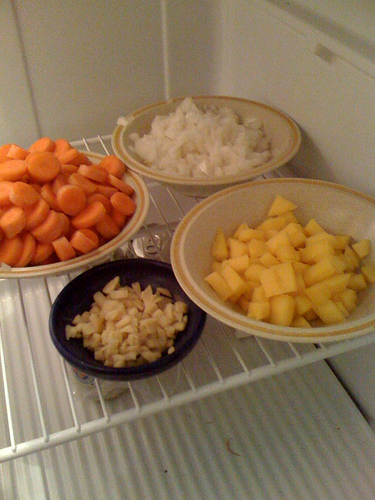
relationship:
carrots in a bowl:
[0, 138, 136, 265] [1, 149, 151, 282]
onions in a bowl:
[133, 99, 270, 180] [114, 95, 304, 190]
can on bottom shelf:
[131, 224, 178, 259] [1, 282, 371, 496]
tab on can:
[143, 233, 161, 251] [131, 224, 178, 259]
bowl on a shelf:
[49, 258, 204, 378] [1, 128, 373, 460]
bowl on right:
[114, 95, 304, 190] [154, 78, 374, 408]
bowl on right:
[171, 180, 374, 344] [154, 78, 374, 408]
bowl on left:
[1, 149, 151, 282] [0, 139, 197, 497]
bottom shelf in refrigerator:
[1, 282, 371, 496] [4, 2, 367, 496]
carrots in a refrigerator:
[0, 138, 136, 265] [4, 2, 367, 496]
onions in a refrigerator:
[133, 99, 270, 180] [4, 2, 367, 496]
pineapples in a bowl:
[206, 198, 368, 327] [171, 180, 374, 344]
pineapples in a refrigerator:
[206, 198, 368, 327] [4, 2, 367, 496]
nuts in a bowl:
[64, 277, 189, 365] [49, 258, 204, 378]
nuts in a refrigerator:
[64, 277, 189, 365] [4, 2, 367, 496]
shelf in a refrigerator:
[1, 128, 373, 460] [4, 2, 367, 496]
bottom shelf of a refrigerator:
[1, 282, 371, 496] [4, 2, 367, 496]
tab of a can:
[143, 233, 161, 251] [131, 224, 178, 259]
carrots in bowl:
[0, 138, 136, 265] [1, 149, 151, 282]